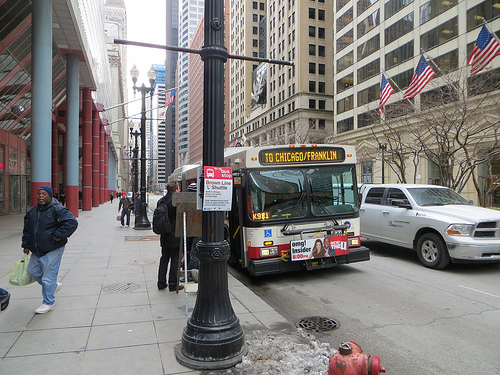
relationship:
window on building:
[354, 20, 379, 35] [327, 20, 495, 156]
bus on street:
[162, 140, 373, 283] [144, 190, 494, 369]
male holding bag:
[20, 186, 76, 315] [8, 245, 37, 286]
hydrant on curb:
[322, 337, 390, 373] [228, 266, 343, 372]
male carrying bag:
[20, 185, 80, 315] [8, 249, 43, 286]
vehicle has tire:
[355, 176, 498, 268] [413, 225, 449, 268]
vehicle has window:
[355, 176, 498, 268] [362, 184, 411, 209]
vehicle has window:
[355, 176, 498, 268] [364, 185, 389, 201]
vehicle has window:
[355, 184, 498, 270] [408, 180, 473, 207]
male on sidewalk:
[20, 186, 76, 315] [2, 231, 165, 372]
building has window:
[330, 14, 499, 194] [382, 38, 418, 68]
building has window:
[330, 14, 499, 194] [353, 54, 380, 79]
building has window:
[330, 14, 499, 194] [353, 60, 380, 85]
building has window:
[215, 11, 327, 143] [308, 22, 324, 42]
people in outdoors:
[13, 173, 185, 320] [12, 134, 219, 337]